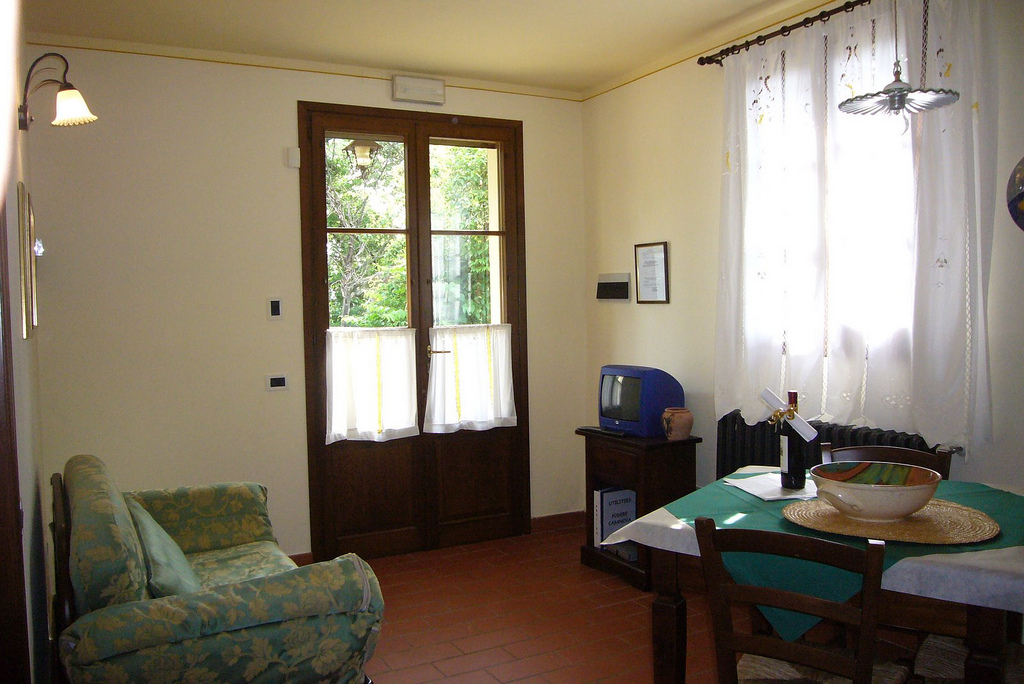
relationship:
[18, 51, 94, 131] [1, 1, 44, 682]
light fixture on wall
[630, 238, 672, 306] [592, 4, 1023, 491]
picture frame on wall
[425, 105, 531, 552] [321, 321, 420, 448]
door with curtain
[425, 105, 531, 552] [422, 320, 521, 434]
door with curtain